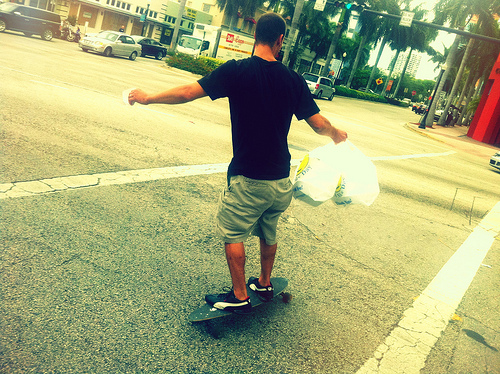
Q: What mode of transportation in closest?
A: Skateboard.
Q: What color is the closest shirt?
A: Black.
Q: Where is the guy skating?
A: On the street.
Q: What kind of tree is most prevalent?
A: Palm.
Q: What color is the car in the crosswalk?
A: White.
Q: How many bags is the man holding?
A: 2.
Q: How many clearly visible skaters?
A: 1.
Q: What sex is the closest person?
A: Male.